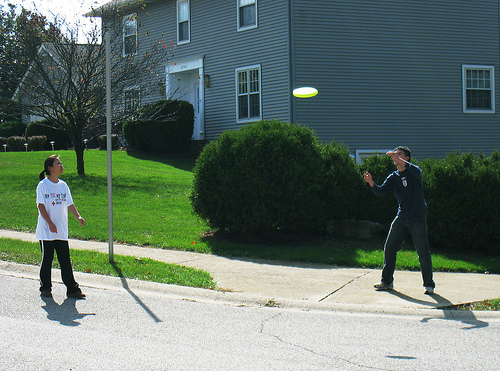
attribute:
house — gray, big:
[81, 2, 500, 162]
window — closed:
[118, 11, 141, 60]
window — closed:
[173, 1, 194, 52]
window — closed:
[230, 2, 263, 35]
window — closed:
[118, 85, 142, 127]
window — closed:
[230, 63, 266, 124]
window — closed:
[459, 61, 499, 119]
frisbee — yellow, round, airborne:
[289, 83, 322, 99]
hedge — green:
[121, 97, 195, 160]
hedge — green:
[187, 118, 327, 246]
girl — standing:
[32, 151, 99, 304]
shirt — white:
[34, 175, 76, 245]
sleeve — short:
[65, 184, 77, 211]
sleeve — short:
[34, 186, 48, 211]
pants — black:
[36, 239, 81, 296]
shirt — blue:
[364, 161, 433, 221]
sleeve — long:
[367, 170, 395, 200]